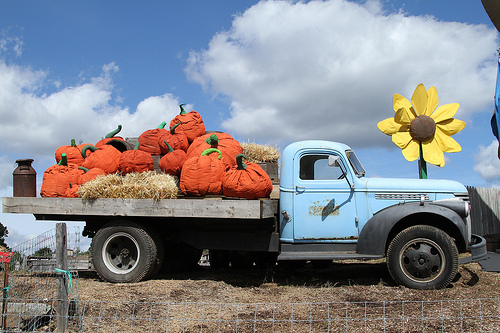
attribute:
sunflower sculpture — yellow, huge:
[376, 84, 464, 176]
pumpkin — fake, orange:
[174, 147, 231, 193]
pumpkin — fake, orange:
[178, 147, 226, 196]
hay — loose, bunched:
[78, 169, 180, 204]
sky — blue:
[9, 0, 488, 237]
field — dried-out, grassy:
[3, 265, 498, 329]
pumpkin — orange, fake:
[137, 116, 192, 151]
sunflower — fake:
[382, 86, 463, 167]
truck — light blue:
[5, 104, 485, 290]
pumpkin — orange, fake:
[164, 97, 208, 141]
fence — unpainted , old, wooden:
[460, 185, 499, 253]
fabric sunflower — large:
[375, 84, 463, 178]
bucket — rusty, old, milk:
[4, 157, 84, 238]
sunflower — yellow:
[380, 76, 472, 191]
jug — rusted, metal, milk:
[0, 134, 43, 216]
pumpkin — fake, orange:
[133, 121, 252, 191]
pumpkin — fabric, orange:
[176, 139, 240, 192]